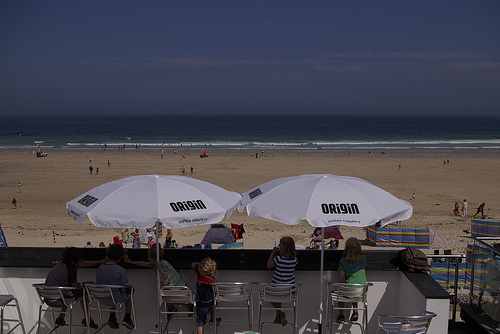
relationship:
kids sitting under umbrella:
[43, 236, 366, 332] [65, 173, 242, 332]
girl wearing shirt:
[336, 237, 366, 289] [350, 262, 366, 282]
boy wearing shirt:
[91, 242, 135, 327] [95, 263, 125, 300]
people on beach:
[113, 228, 333, 248] [78, 158, 283, 178]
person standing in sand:
[8, 194, 26, 211] [4, 168, 60, 228]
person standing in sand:
[459, 197, 470, 217] [4, 147, 496, 256]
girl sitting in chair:
[336, 237, 367, 323] [327, 271, 367, 332]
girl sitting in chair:
[336, 237, 367, 323] [327, 280, 372, 332]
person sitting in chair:
[122, 245, 194, 315] [156, 282, 196, 330]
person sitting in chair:
[266, 233, 300, 300] [258, 284, 296, 328]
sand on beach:
[216, 160, 280, 177] [1, 142, 498, 253]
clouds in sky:
[89, 47, 499, 82] [4, 0, 498, 120]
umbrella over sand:
[66, 175, 242, 334] [8, 155, 498, 258]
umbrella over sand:
[233, 167, 415, 231] [4, 147, 496, 256]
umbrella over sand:
[62, 169, 243, 234] [4, 147, 496, 256]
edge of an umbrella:
[303, 180, 323, 220] [236, 172, 413, 229]